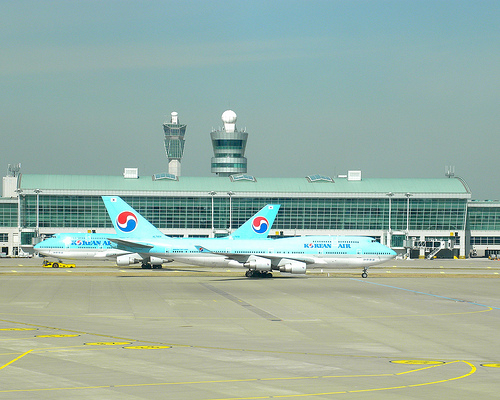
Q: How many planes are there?
A: Two.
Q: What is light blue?
A: Planes.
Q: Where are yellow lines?
A: On the ground.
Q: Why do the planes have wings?
A: To fly.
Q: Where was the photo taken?
A: At the airport.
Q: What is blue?
A: Sky.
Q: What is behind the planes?
A: A building.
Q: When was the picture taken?
A: Daytime.